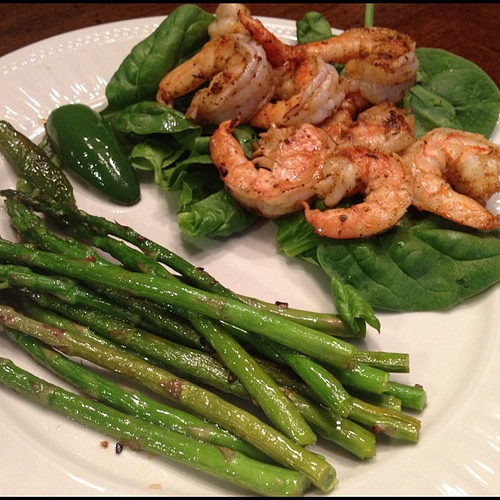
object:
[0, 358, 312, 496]
asparagus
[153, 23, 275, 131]
shrimp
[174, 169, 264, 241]
veggies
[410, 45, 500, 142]
veggies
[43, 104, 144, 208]
pepper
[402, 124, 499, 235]
shrimp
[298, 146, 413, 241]
shrimp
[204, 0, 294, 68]
shrimp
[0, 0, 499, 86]
table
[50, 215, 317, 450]
stem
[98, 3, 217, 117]
leaf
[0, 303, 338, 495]
asparagus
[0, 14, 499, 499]
surface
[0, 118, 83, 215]
food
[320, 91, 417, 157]
shrimps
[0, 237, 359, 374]
asparagus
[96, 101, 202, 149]
spinach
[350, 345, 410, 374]
stick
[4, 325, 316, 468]
stick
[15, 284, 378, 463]
stick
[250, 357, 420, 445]
stick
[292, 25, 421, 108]
shrimp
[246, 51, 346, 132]
shrimp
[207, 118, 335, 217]
shrimp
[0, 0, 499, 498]
plate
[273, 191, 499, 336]
spinach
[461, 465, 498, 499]
light